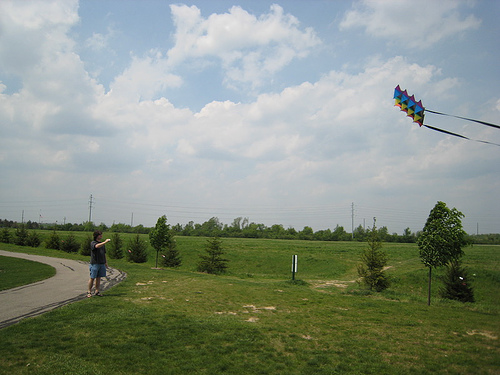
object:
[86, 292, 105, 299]
feet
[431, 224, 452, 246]
leaves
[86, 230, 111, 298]
man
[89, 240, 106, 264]
shirt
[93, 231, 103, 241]
hair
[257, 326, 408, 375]
grass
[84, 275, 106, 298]
wearing shoes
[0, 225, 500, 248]
line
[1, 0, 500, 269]
background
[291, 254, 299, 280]
back sign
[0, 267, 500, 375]
meadow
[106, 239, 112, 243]
hand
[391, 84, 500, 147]
colorful kite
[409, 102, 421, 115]
colorful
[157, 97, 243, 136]
white clouds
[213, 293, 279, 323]
dirt patch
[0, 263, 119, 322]
ground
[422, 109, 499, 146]
string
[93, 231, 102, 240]
head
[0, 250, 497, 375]
field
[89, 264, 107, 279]
shorts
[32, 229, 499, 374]
green prairie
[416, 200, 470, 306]
tree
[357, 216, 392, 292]
tree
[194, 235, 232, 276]
tree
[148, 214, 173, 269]
tree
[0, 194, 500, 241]
power lines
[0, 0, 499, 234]
sky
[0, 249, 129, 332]
road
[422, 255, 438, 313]
trunk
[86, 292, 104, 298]
shoes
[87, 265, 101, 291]
legs